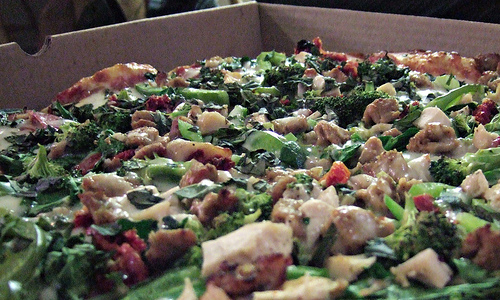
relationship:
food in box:
[1, 28, 498, 284] [0, 3, 500, 112]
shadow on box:
[257, 6, 291, 49] [6, 5, 496, 289]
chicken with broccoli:
[2, 46, 498, 298] [0, 33, 500, 298]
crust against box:
[56, 62, 155, 105] [0, 2, 500, 110]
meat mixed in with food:
[0, 37, 500, 300] [1, 28, 498, 284]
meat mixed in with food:
[207, 241, 294, 283] [1, 28, 498, 284]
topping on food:
[101, 176, 213, 281] [0, 37, 497, 300]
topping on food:
[0, 37, 500, 300] [0, 37, 497, 300]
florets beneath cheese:
[0, 38, 500, 300] [242, 60, 257, 82]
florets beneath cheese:
[192, 67, 223, 89] [242, 60, 257, 82]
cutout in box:
[14, 36, 51, 57] [0, 3, 500, 112]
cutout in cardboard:
[14, 30, 65, 67] [0, 0, 273, 109]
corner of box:
[247, 10, 277, 46] [19, 8, 490, 143]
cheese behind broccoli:
[371, 58, 445, 113] [0, 39, 500, 300]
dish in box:
[6, 62, 494, 294] [262, 5, 494, 57]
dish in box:
[6, 62, 494, 294] [8, 5, 260, 82]